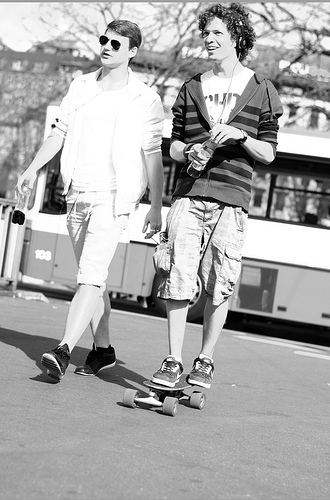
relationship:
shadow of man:
[11, 326, 42, 354] [79, 20, 221, 289]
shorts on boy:
[152, 194, 247, 305] [150, 0, 284, 391]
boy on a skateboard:
[150, 0, 284, 391] [125, 374, 207, 414]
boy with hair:
[150, 0, 284, 391] [225, 5, 253, 36]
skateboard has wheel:
[147, 339, 221, 440] [158, 394, 179, 417]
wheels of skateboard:
[115, 384, 182, 418] [138, 371, 205, 404]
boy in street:
[150, 0, 284, 391] [0, 294, 328, 498]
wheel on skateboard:
[187, 387, 208, 410] [119, 369, 210, 417]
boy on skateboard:
[150, 0, 284, 391] [120, 373, 206, 411]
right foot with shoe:
[148, 352, 184, 389] [111, 342, 213, 399]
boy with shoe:
[150, 4, 284, 391] [111, 342, 213, 399]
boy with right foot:
[150, 4, 284, 391] [148, 352, 184, 389]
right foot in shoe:
[148, 352, 184, 389] [111, 342, 213, 399]